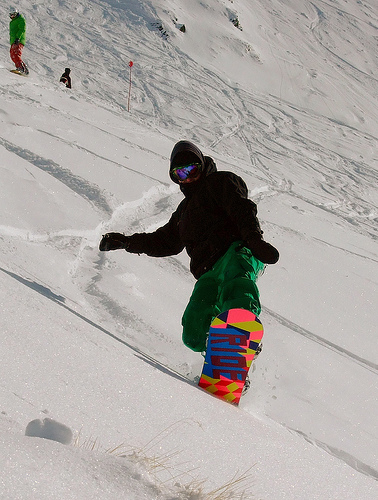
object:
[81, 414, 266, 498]
grass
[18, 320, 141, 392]
snow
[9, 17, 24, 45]
coat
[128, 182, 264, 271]
black jacket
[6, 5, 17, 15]
helmet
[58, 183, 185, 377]
trail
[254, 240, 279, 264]
mitten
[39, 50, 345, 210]
marks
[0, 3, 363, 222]
snow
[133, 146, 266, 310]
athletes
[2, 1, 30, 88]
athletes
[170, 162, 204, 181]
goggles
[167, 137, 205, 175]
hat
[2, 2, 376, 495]
doesn't match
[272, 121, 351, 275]
snow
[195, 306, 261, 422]
snow board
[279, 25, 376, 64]
no subject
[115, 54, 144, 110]
pole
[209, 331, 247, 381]
word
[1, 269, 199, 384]
shadow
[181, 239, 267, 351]
green pants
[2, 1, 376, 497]
snow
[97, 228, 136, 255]
black gloves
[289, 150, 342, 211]
clouds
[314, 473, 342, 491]
sky